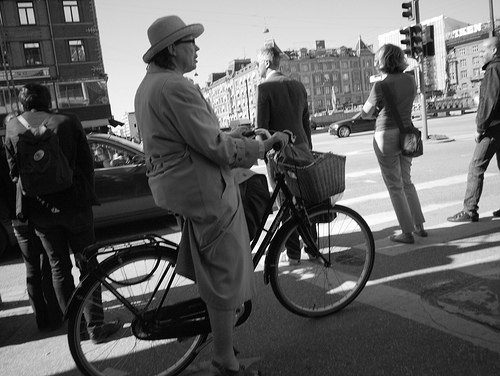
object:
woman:
[359, 44, 429, 244]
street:
[0, 111, 497, 376]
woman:
[132, 12, 288, 376]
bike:
[63, 128, 375, 374]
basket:
[268, 147, 347, 203]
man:
[444, 37, 496, 223]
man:
[3, 82, 119, 345]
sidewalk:
[0, 243, 500, 376]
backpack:
[11, 113, 73, 195]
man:
[251, 43, 319, 266]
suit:
[256, 74, 312, 148]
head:
[481, 37, 498, 60]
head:
[373, 42, 412, 75]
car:
[0, 130, 169, 242]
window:
[88, 137, 139, 169]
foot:
[387, 234, 420, 245]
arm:
[360, 81, 388, 119]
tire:
[260, 207, 377, 320]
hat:
[134, 14, 202, 62]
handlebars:
[260, 134, 291, 157]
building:
[2, 0, 109, 155]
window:
[60, 2, 80, 25]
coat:
[133, 67, 267, 312]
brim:
[151, 25, 190, 43]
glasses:
[175, 34, 192, 49]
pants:
[35, 209, 121, 345]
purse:
[396, 123, 422, 157]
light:
[400, 1, 439, 140]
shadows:
[337, 206, 500, 275]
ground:
[0, 105, 500, 375]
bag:
[280, 141, 311, 174]